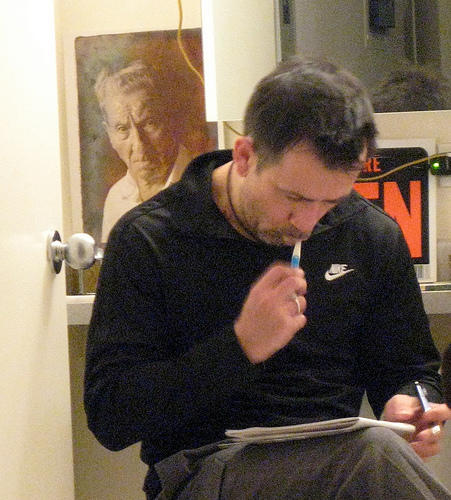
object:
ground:
[375, 134, 384, 139]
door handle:
[50, 229, 104, 273]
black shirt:
[82, 150, 444, 497]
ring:
[289, 293, 300, 313]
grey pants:
[153, 424, 450, 500]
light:
[432, 162, 439, 170]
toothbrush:
[291, 241, 302, 268]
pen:
[291, 241, 301, 268]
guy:
[83, 56, 449, 500]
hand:
[238, 261, 308, 361]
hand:
[384, 393, 450, 463]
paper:
[219, 417, 416, 448]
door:
[0, 0, 75, 500]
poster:
[75, 26, 208, 292]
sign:
[353, 146, 428, 263]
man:
[96, 61, 192, 243]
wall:
[55, 0, 451, 500]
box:
[429, 155, 451, 177]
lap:
[218, 417, 416, 450]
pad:
[223, 423, 397, 500]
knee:
[344, 427, 409, 500]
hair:
[241, 53, 381, 174]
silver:
[49, 230, 96, 274]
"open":
[351, 180, 421, 258]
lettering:
[353, 154, 422, 258]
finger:
[260, 262, 308, 326]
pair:
[154, 422, 423, 500]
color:
[152, 246, 212, 391]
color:
[228, 65, 242, 111]